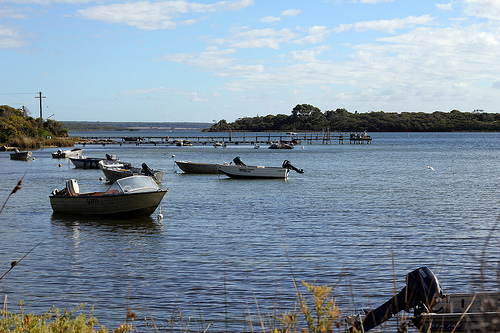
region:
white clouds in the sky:
[193, 12, 430, 82]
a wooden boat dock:
[73, 115, 377, 160]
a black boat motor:
[349, 245, 444, 331]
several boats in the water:
[9, 133, 311, 243]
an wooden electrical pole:
[16, 82, 57, 134]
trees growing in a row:
[189, 92, 484, 139]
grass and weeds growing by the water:
[293, 275, 388, 331]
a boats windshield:
[103, 172, 156, 200]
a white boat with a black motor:
[183, 151, 310, 183]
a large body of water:
[214, 158, 471, 263]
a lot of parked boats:
[20, 126, 332, 256]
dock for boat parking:
[42, 93, 382, 155]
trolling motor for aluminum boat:
[322, 247, 447, 332]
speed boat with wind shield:
[23, 167, 175, 230]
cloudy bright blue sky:
[41, 23, 403, 133]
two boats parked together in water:
[166, 152, 326, 196]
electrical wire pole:
[29, 84, 54, 126]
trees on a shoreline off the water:
[196, 85, 478, 157]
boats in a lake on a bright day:
[93, 29, 357, 260]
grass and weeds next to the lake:
[246, 233, 480, 332]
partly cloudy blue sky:
[96, 2, 488, 102]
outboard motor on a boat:
[338, 257, 440, 325]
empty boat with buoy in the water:
[36, 164, 172, 234]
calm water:
[288, 173, 492, 253]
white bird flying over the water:
[420, 162, 440, 175]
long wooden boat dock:
[63, 119, 378, 156]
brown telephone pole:
[28, 76, 53, 133]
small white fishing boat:
[208, 149, 308, 186]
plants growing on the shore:
[0, 286, 349, 327]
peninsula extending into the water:
[196, 87, 498, 136]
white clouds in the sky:
[277, 11, 374, 58]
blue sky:
[103, 24, 152, 75]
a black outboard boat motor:
[344, 246, 449, 323]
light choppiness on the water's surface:
[216, 197, 321, 259]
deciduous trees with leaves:
[243, 100, 418, 129]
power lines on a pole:
[8, 74, 70, 119]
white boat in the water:
[32, 168, 180, 228]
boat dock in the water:
[153, 120, 384, 159]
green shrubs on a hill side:
[7, 114, 44, 144]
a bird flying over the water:
[399, 150, 466, 189]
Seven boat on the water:
[7, 145, 314, 247]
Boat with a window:
[46, 169, 176, 227]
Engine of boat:
[41, 170, 82, 202]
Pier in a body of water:
[68, 125, 380, 149]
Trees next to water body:
[200, 97, 499, 135]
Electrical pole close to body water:
[31, 86, 52, 146]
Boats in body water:
[1, 78, 498, 323]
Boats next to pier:
[118, 137, 318, 151]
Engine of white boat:
[281, 157, 310, 177]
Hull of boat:
[48, 192, 163, 219]